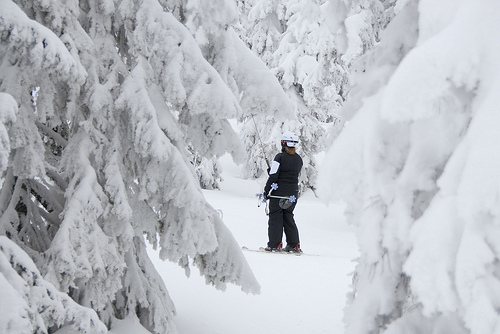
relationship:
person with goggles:
[262, 132, 306, 258] [281, 138, 300, 147]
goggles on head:
[281, 138, 300, 147] [278, 133, 302, 155]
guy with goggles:
[262, 132, 306, 258] [281, 138, 300, 147]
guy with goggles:
[263, 131, 303, 252] [281, 138, 300, 147]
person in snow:
[262, 132, 306, 258] [211, 188, 350, 330]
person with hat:
[262, 132, 306, 258] [279, 131, 302, 142]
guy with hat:
[263, 131, 303, 252] [279, 131, 302, 142]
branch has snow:
[119, 65, 260, 293] [123, 68, 205, 234]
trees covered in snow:
[3, 4, 281, 305] [123, 68, 205, 234]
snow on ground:
[211, 188, 350, 330] [138, 188, 343, 332]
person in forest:
[262, 132, 306, 258] [3, 16, 496, 331]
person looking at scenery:
[262, 132, 306, 258] [25, 10, 360, 228]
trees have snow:
[3, 4, 281, 305] [123, 68, 205, 234]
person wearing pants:
[262, 132, 306, 258] [266, 194, 302, 248]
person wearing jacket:
[262, 132, 306, 258] [264, 153, 309, 197]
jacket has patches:
[264, 153, 309, 197] [268, 161, 280, 174]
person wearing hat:
[262, 132, 306, 258] [279, 131, 302, 142]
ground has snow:
[138, 188, 343, 332] [211, 188, 350, 330]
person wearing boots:
[262, 132, 306, 258] [267, 239, 303, 252]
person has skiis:
[262, 132, 306, 258] [242, 240, 323, 260]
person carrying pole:
[262, 132, 306, 258] [247, 108, 274, 176]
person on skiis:
[262, 132, 306, 258] [242, 240, 323, 260]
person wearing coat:
[262, 132, 306, 258] [263, 154, 304, 197]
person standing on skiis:
[262, 132, 306, 258] [242, 240, 323, 260]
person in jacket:
[262, 132, 306, 258] [264, 153, 309, 197]